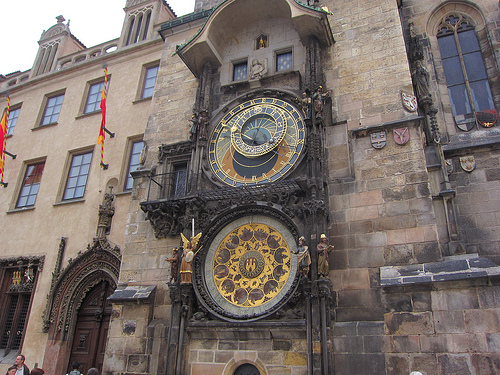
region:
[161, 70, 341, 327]
The astrological clock on the building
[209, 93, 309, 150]
The clock is blue and gold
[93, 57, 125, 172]
The flag on the wall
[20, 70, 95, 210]
The color of the building is brown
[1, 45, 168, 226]
The windows on the side of the building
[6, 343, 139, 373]
The people outside of the building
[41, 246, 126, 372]
The doors to the building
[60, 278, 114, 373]
The door are the color brown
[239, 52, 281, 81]
A statue at the top of the building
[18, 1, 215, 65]
The top of the building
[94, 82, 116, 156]
a red and yellow flag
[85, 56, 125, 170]
a red and yellow flag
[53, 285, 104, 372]
a brown wooden door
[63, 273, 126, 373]
a brown wooden door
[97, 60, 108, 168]
rolled up yellow and red flag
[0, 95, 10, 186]
rolled up yellow and red flag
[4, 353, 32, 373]
person walking on street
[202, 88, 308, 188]
clock with astronomical artifact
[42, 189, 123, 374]
heavily decorated porch with wooden door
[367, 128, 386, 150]
coats of arms shield on brick wall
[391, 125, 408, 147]
coats of arms shield on brick wall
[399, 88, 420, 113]
coats of arms shield on brick wall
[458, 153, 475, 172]
coats of arms shield on brick wall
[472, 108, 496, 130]
coats of arms shield on brick wall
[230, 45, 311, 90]
The cherub is between the windows.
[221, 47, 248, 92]
The window is closed.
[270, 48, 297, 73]
The window is closed.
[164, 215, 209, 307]
The angel is next to the clock.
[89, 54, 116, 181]
The flag is very still.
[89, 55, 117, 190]
The flag is red and yellow.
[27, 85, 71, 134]
The window is closed.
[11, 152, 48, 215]
The window is closed.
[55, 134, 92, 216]
The window is closed.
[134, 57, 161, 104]
The window is closed.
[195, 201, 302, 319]
gold ornate medallion ornamentation on side of building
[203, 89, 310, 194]
round gold compass clock on side of building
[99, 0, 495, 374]
stone building made from stone blocks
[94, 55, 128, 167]
orange and yellow flags hanging from side of building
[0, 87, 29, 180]
orange and yellow flag hanging from building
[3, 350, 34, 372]
man wearing glasses standing near building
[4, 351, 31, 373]
man wearing blue shirt standing near building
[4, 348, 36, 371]
man in dark jacket standing near building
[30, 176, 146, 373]
carved ornate archway over wooden door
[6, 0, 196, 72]
white bright sunny cloudless sky